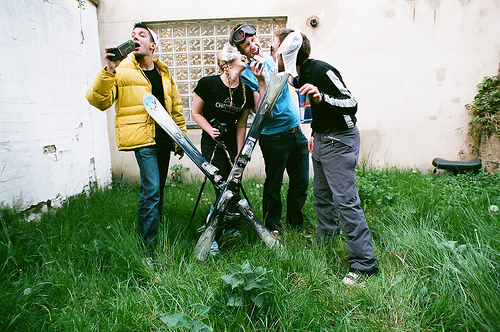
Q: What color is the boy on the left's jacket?
A: Yellow.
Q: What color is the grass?
A: Green.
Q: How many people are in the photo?
A: 4.